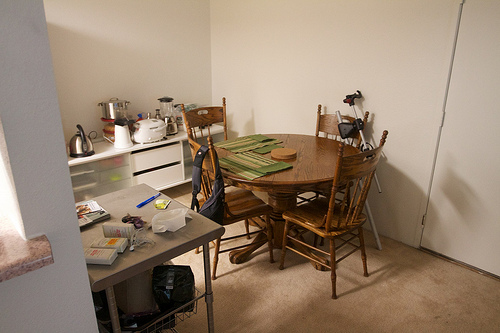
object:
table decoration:
[270, 147, 298, 159]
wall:
[36, 0, 500, 281]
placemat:
[213, 134, 282, 154]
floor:
[161, 225, 500, 333]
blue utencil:
[136, 193, 161, 208]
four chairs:
[171, 101, 388, 300]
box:
[114, 124, 134, 150]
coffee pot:
[69, 124, 97, 159]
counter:
[67, 122, 225, 167]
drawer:
[130, 143, 183, 174]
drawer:
[133, 163, 184, 191]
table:
[198, 130, 365, 270]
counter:
[76, 183, 224, 333]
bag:
[191, 144, 226, 227]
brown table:
[202, 133, 365, 273]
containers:
[91, 237, 128, 254]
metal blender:
[156, 96, 179, 137]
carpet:
[140, 180, 497, 333]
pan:
[97, 97, 131, 120]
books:
[217, 151, 292, 182]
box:
[81, 248, 117, 265]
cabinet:
[71, 131, 227, 206]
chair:
[296, 103, 369, 206]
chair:
[278, 130, 389, 299]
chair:
[185, 129, 276, 282]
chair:
[179, 96, 228, 143]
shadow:
[303, 157, 443, 284]